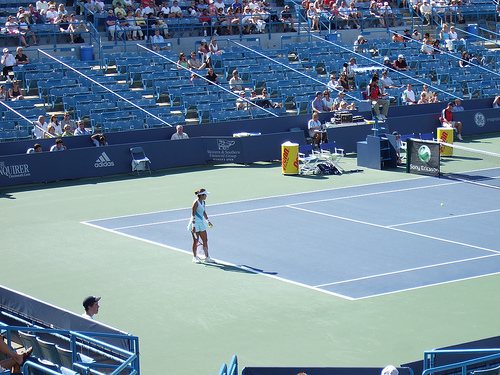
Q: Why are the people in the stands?
A: They are watching a tennis match.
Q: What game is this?
A: Tennis.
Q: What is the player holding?
A: A racket.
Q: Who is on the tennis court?
A: A tennis player.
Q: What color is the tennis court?
A: Blue.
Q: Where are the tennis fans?
A: In the stands.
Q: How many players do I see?
A: One.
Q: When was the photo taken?
A: During the day.